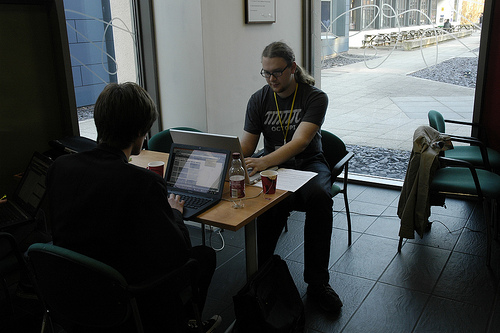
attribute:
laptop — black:
[151, 140, 241, 222]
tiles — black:
[359, 241, 499, 331]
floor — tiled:
[316, 189, 498, 331]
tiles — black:
[327, 237, 389, 278]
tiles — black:
[385, 240, 440, 292]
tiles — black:
[363, 184, 387, 209]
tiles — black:
[356, 282, 423, 332]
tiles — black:
[435, 251, 488, 300]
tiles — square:
[315, 237, 475, 307]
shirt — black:
[242, 80, 330, 170]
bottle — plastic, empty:
[228, 150, 248, 212]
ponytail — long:
[292, 62, 317, 89]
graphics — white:
[316, 3, 483, 80]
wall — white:
[162, 9, 237, 127]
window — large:
[293, 2, 482, 187]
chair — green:
[417, 104, 498, 165]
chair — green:
[382, 113, 498, 262]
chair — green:
[397, 124, 491, 253]